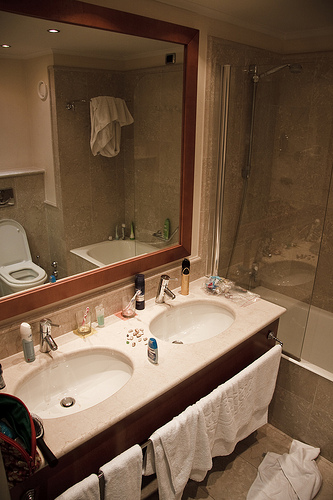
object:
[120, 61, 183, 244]
wall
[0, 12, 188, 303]
mirror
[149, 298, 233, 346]
sink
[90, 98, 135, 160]
towel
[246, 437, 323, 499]
towel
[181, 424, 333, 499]
floor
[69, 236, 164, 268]
tub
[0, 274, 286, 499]
counter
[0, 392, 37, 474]
bag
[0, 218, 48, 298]
toilet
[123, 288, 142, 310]
brush